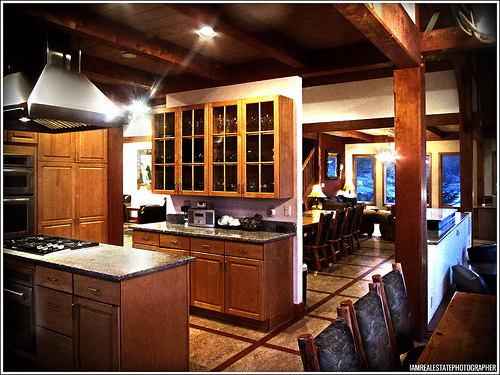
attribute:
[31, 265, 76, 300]
drawer — wooden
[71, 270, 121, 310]
drawer — wooden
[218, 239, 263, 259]
drawer — wooden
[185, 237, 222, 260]
drawer — wooden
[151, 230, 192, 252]
drawer — wooden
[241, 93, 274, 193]
door — glass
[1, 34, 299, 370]
kitchen — wooden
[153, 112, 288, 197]
glass cabinet-doors — glass 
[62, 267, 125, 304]
drawer — wooden